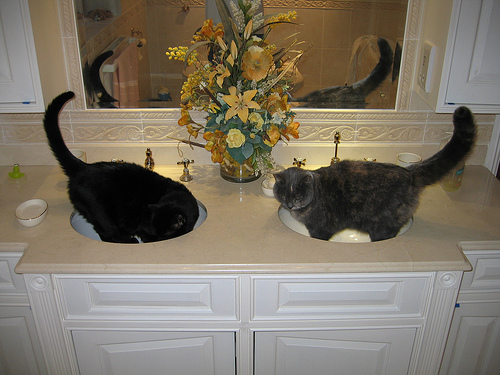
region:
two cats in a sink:
[23, 73, 497, 342]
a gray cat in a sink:
[254, 103, 487, 257]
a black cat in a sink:
[36, 85, 213, 258]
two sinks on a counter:
[29, 149, 454, 273]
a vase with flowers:
[161, 5, 308, 185]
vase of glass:
[216, 133, 268, 184]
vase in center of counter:
[34, 5, 465, 265]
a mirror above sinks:
[64, 5, 435, 125]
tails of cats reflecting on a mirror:
[71, 34, 408, 107]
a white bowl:
[11, 194, 53, 229]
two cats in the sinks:
[36, 81, 487, 256]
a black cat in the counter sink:
[45, 83, 209, 248]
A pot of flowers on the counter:
[186, 0, 294, 182]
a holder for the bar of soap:
[12, 193, 54, 231]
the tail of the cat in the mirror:
[83, 44, 124, 104]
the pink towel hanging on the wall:
[108, 46, 143, 107]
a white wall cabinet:
[1, 1, 64, 111]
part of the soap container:
[444, 156, 468, 195]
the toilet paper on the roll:
[133, 33, 149, 60]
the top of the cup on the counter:
[392, 145, 424, 168]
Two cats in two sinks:
[20, 83, 497, 258]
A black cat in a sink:
[38, 83, 200, 253]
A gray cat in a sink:
[265, 93, 482, 243]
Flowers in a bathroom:
[142, 8, 322, 177]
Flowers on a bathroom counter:
[162, 5, 312, 187]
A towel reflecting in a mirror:
[105, 43, 152, 110]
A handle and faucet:
[136, 143, 203, 180]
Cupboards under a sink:
[17, 264, 477, 371]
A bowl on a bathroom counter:
[7, 193, 54, 233]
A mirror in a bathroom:
[54, 3, 432, 123]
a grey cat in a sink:
[270, 102, 475, 242]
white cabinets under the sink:
[23, 270, 462, 372]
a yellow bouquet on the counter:
[170, 0, 303, 177]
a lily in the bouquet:
[215, 79, 262, 124]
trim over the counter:
[2, 114, 489, 149]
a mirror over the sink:
[71, 2, 413, 104]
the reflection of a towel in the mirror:
[100, 24, 150, 106]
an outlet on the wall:
[412, 40, 437, 92]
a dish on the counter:
[10, 197, 47, 229]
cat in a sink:
[52, 175, 199, 249]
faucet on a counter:
[170, 152, 202, 178]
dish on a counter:
[10, 192, 55, 230]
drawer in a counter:
[241, 270, 441, 330]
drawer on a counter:
[50, 265, 240, 331]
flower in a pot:
[170, 13, 300, 153]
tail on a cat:
[403, 105, 477, 180]